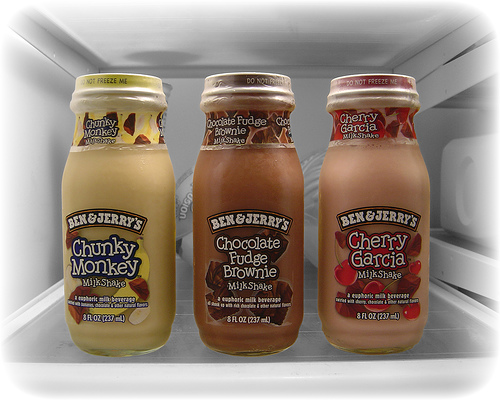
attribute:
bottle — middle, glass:
[190, 70, 305, 357]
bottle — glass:
[317, 72, 428, 351]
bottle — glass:
[61, 73, 176, 357]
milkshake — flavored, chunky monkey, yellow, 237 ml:
[62, 113, 176, 351]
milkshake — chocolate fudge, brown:
[193, 103, 306, 353]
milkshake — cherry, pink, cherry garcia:
[319, 103, 431, 352]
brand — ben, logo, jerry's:
[66, 207, 149, 242]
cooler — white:
[6, 4, 496, 386]